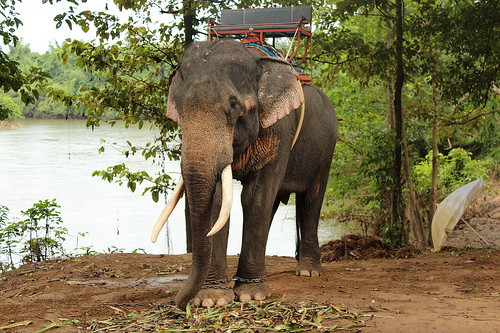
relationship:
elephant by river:
[163, 18, 323, 271] [77, 116, 245, 259]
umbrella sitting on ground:
[428, 177, 497, 255] [2, 255, 498, 330]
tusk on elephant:
[202, 166, 232, 240] [152, 32, 344, 309]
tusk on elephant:
[145, 176, 187, 242] [152, 32, 344, 309]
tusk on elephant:
[147, 176, 188, 242] [128, 0, 356, 330]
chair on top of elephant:
[209, 11, 319, 62] [152, 32, 344, 309]